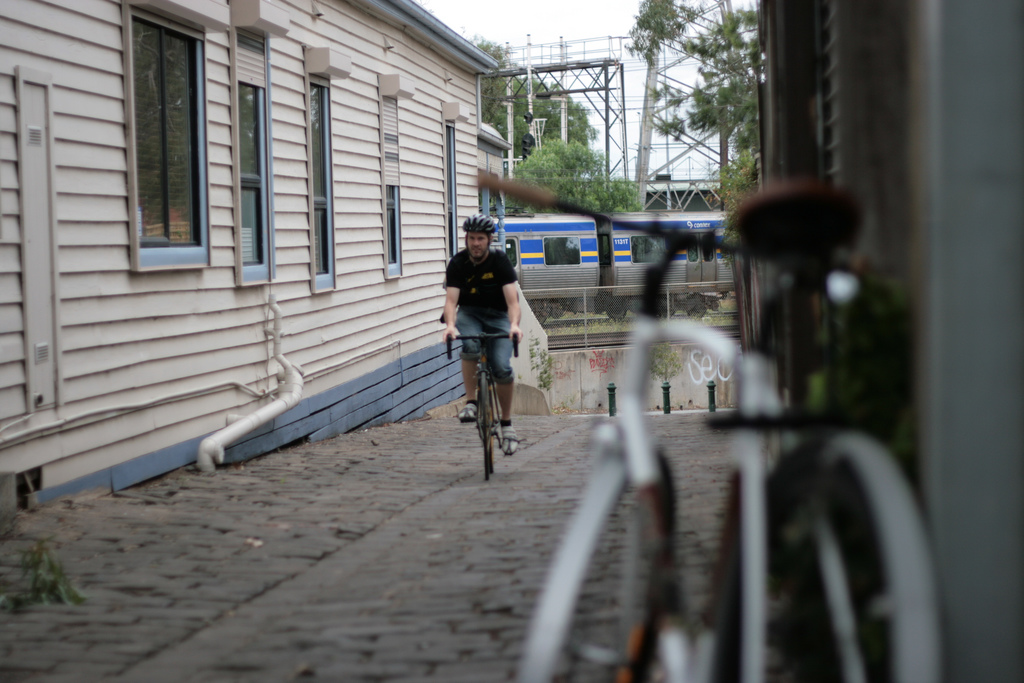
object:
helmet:
[462, 211, 497, 233]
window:
[109, 2, 215, 278]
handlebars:
[444, 329, 521, 362]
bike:
[473, 160, 943, 682]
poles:
[606, 382, 618, 417]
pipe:
[184, 290, 315, 472]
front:
[475, 370, 498, 480]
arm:
[498, 260, 525, 328]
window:
[226, 34, 280, 290]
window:
[541, 234, 582, 266]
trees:
[504, 135, 632, 225]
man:
[440, 214, 518, 479]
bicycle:
[446, 330, 517, 477]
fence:
[520, 283, 741, 351]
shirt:
[446, 247, 520, 321]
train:
[492, 212, 749, 302]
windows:
[374, 66, 418, 287]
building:
[0, 0, 506, 518]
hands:
[439, 329, 460, 344]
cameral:
[0, 0, 1024, 680]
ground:
[0, 409, 760, 682]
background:
[399, 0, 779, 420]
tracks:
[495, 300, 743, 351]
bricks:
[135, 511, 220, 559]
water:
[197, 292, 302, 479]